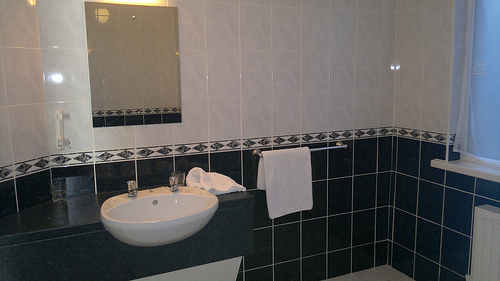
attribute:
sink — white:
[96, 184, 226, 249]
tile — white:
[0, 1, 470, 181]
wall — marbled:
[0, 1, 496, 279]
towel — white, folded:
[256, 146, 314, 221]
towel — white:
[184, 165, 251, 195]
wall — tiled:
[212, 17, 429, 120]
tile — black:
[336, 171, 394, 222]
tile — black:
[302, 55, 332, 84]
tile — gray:
[323, 47, 360, 94]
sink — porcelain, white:
[101, 185, 217, 245]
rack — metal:
[242, 132, 362, 160]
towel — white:
[246, 146, 321, 231]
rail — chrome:
[245, 140, 347, 154]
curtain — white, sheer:
[461, 19, 495, 165]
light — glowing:
[85, 3, 177, 10]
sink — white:
[99, 181, 215, 248]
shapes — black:
[266, 124, 411, 144]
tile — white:
[241, 98, 270, 138]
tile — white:
[175, 95, 206, 143]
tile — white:
[46, 103, 93, 153]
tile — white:
[43, 48, 90, 103]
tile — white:
[37, 0, 85, 48]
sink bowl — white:
[115, 190, 225, 222]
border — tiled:
[6, 121, 480, 192]